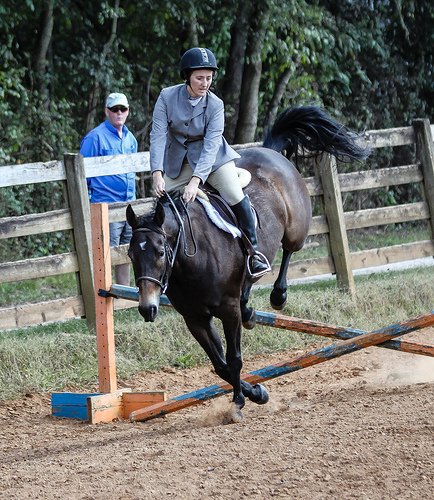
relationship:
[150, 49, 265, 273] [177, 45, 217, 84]
girl wearing hat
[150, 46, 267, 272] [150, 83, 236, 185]
girl wearing jacket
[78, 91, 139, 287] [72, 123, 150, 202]
man wearing shirt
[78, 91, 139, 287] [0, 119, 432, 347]
man standing behind fence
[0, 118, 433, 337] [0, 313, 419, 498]
fence posted in ground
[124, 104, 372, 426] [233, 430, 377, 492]
horse galloping on path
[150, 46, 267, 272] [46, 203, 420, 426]
girl jumping over post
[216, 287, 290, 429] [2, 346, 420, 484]
hooves are galloping across dirt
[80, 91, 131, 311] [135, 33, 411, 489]
man watching competition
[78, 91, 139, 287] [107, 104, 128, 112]
man wearing dark glasses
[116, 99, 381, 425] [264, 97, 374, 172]
horse waving tail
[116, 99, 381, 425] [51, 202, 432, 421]
horse jumping over jump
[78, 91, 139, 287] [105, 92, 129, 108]
man wearing cap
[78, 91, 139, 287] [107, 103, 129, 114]
man wearing sunglasses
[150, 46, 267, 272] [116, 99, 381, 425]
girl riding horse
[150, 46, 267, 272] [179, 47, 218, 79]
girl wearing hat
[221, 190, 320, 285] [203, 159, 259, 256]
boot being worn on leg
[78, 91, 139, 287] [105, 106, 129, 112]
man wearing dark glasses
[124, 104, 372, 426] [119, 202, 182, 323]
horse has a large head.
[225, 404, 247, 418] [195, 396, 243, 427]
hoof kicking up dirt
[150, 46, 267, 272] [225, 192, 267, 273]
girl wearing boot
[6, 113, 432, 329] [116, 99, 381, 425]
fence behind horse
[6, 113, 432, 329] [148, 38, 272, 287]
fence behind rider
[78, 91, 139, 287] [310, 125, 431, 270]
man standing by fence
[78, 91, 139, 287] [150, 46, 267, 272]
man watching girl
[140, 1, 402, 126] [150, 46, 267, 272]
trees are behind girl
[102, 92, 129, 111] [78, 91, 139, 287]
cap on man